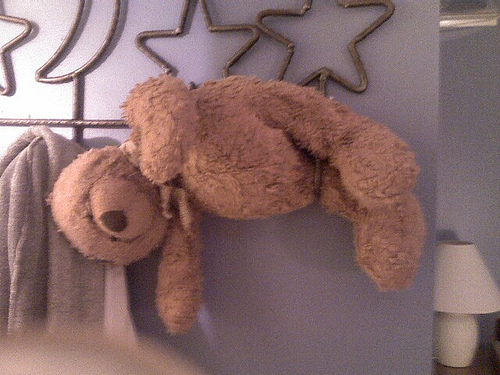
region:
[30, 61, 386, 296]
teddy bear in the photo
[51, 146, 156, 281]
head of the teddy bear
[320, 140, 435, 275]
legs of the teddy beat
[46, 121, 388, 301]
brown teddy bear on wall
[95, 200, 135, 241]
nose of the teddy bear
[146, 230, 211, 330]
arm of the teddy bear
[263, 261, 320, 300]
wall behind the teddy bear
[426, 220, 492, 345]
lamp in the room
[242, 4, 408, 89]
star shape on the wall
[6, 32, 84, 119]
light hitting the wall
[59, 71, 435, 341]
a teddy bear hanging in the wall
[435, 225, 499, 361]
night lamp kept in the table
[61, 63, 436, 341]
brown color teddy bear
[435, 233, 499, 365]
white colour night lamp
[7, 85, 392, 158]
metal rod with teddy bear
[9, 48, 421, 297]
metal rod and teddy bear attached in the wall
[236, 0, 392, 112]
star shaped metal rod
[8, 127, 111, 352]
woolen cloth hanging in the wall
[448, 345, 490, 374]
wooden side table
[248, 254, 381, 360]
a plain wall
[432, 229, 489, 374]
white color night lamp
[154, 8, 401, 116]
a star shaped metal rod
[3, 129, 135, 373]
a woolen cloth hanging in the wall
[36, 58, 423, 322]
a teddy bear hanging in the wall with metal rod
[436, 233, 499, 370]
a table with night lamp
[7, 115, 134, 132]
metal rod attached with the wall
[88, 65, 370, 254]
teddy bear, metal rod attached with the wall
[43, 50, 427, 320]
the teddy bear is hanging on a hook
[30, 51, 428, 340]
the teddy is brown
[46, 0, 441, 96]
stars & the moon are visible on the coat rack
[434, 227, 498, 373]
a small white lamp sits to the right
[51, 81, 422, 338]
the poor teddy looks like he has seen better days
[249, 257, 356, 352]
the background color is a pale lavender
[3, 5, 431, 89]
the stars & moon are made from iron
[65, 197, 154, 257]
the teddy's nose & eyes are dark brown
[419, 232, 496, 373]
the lamp is setting on a table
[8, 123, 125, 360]
a jacket or a robe hangs on a hook next to teddy.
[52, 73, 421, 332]
A giant teddy bear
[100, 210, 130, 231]
An artificial nose on a stuffed bear.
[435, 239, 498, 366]
A white lamp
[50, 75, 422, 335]
A fluffy bear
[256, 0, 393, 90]
A star decoration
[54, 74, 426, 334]
A stuffed animal that is a bear.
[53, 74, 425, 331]
A brown bear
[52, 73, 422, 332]
Brown bear hanging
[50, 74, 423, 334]
A bear on the wall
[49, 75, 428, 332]
An adorable stitched up bear